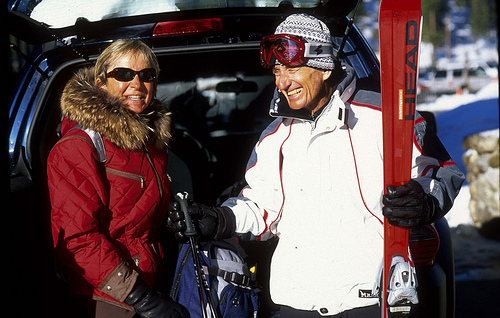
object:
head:
[94, 36, 161, 113]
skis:
[373, 0, 420, 317]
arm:
[42, 137, 145, 306]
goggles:
[257, 35, 308, 76]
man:
[165, 14, 468, 317]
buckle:
[217, 266, 252, 288]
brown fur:
[57, 67, 180, 155]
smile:
[284, 85, 309, 100]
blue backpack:
[167, 238, 270, 318]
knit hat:
[273, 13, 338, 74]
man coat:
[217, 66, 467, 318]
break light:
[152, 17, 224, 39]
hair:
[92, 37, 162, 85]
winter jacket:
[43, 66, 172, 314]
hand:
[379, 178, 438, 228]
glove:
[380, 177, 435, 228]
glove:
[120, 284, 192, 318]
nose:
[276, 68, 294, 91]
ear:
[93, 77, 107, 91]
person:
[46, 37, 195, 317]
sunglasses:
[105, 65, 159, 82]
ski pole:
[173, 191, 219, 318]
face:
[270, 60, 324, 110]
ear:
[319, 69, 333, 81]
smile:
[122, 92, 146, 101]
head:
[271, 12, 334, 110]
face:
[101, 47, 155, 114]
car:
[0, 0, 461, 317]